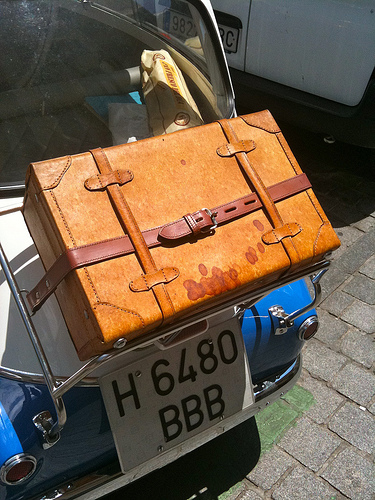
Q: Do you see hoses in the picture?
A: No, there are no hoses.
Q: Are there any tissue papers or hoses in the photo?
A: No, there are no hoses or tissue papers.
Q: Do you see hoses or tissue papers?
A: No, there are no hoses or tissue papers.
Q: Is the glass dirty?
A: Yes, the glass is dirty.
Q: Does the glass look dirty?
A: Yes, the glass is dirty.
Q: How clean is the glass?
A: The glass is dirty.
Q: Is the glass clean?
A: No, the glass is dirty.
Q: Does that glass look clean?
A: No, the glass is dirty.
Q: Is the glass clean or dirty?
A: The glass is dirty.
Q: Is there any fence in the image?
A: No, there are no fences.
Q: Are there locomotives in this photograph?
A: No, there are no locomotives.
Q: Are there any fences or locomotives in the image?
A: No, there are no locomotives or fences.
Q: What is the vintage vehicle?
A: The vehicle is a car.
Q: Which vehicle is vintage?
A: The vehicle is a car.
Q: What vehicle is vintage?
A: The vehicle is a car.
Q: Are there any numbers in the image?
A: Yes, there are numbers.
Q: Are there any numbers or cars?
A: Yes, there are numbers.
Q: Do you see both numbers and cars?
A: Yes, there are both numbers and a car.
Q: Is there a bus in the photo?
A: No, there are no buses.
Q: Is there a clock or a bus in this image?
A: No, there are no buses or clocks.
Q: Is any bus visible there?
A: No, there are no buses.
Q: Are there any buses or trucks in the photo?
A: No, there are no buses or trucks.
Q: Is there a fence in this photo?
A: No, there are no fences.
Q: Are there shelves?
A: No, there are no shelves.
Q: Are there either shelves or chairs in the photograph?
A: No, there are no shelves or chairs.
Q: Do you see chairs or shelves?
A: No, there are no shelves or chairs.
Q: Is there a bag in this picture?
A: Yes, there is a bag.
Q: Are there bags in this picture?
A: Yes, there is a bag.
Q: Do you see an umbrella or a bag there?
A: Yes, there is a bag.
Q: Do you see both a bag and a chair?
A: No, there is a bag but no chairs.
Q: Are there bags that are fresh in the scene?
A: Yes, there is a fresh bag.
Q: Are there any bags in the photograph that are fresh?
A: Yes, there is a bag that is fresh.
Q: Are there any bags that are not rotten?
A: Yes, there is a fresh bag.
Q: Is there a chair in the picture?
A: No, there are no chairs.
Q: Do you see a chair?
A: No, there are no chairs.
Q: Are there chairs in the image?
A: No, there are no chairs.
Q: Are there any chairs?
A: No, there are no chairs.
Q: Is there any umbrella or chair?
A: No, there are no chairs or umbrellas.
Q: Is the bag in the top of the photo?
A: Yes, the bag is in the top of the image.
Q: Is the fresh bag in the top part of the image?
A: Yes, the bag is in the top of the image.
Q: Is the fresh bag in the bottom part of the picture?
A: No, the bag is in the top of the image.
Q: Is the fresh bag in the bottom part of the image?
A: No, the bag is in the top of the image.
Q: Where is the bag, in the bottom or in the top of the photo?
A: The bag is in the top of the image.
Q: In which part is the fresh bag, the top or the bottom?
A: The bag is in the top of the image.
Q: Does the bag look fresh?
A: Yes, the bag is fresh.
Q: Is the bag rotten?
A: No, the bag is fresh.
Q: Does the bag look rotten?
A: No, the bag is fresh.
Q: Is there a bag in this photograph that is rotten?
A: No, there is a bag but it is fresh.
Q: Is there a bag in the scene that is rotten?
A: No, there is a bag but it is fresh.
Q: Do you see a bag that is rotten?
A: No, there is a bag but it is fresh.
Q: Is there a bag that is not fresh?
A: No, there is a bag but it is fresh.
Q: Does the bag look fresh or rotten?
A: The bag is fresh.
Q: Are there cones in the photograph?
A: No, there are no cones.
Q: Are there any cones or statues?
A: No, there are no cones or statues.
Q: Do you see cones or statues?
A: No, there are no cones or statues.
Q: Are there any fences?
A: No, there are no fences.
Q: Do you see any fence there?
A: No, there are no fences.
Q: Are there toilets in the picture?
A: No, there are no toilets.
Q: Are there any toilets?
A: No, there are no toilets.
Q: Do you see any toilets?
A: No, there are no toilets.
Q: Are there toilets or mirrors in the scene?
A: No, there are no toilets or mirrors.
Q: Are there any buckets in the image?
A: No, there are no buckets.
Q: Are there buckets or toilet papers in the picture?
A: No, there are no buckets or toilet papers.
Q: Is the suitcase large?
A: Yes, the suitcase is large.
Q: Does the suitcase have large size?
A: Yes, the suitcase is large.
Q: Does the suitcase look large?
A: Yes, the suitcase is large.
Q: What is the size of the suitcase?
A: The suitcase is large.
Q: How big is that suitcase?
A: The suitcase is large.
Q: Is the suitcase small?
A: No, the suitcase is large.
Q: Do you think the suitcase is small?
A: No, the suitcase is large.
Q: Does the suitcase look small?
A: No, the suitcase is large.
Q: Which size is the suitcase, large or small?
A: The suitcase is large.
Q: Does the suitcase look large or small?
A: The suitcase is large.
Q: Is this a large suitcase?
A: Yes, this is a large suitcase.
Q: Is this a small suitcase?
A: No, this is a large suitcase.